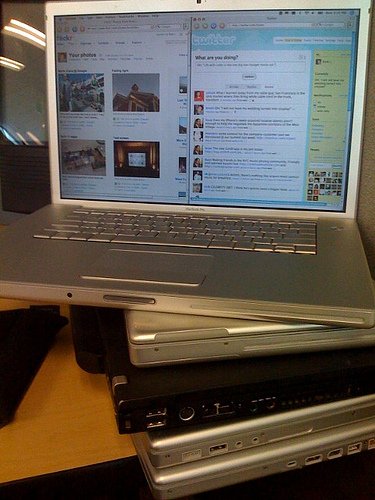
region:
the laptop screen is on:
[53, 9, 347, 208]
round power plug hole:
[178, 406, 194, 424]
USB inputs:
[306, 446, 345, 463]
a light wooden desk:
[2, 331, 134, 482]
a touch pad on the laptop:
[88, 248, 214, 289]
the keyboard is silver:
[36, 204, 318, 253]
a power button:
[330, 224, 342, 230]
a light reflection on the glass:
[2, 21, 43, 73]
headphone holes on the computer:
[235, 437, 258, 447]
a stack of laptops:
[108, 321, 371, 494]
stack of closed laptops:
[100, 308, 373, 499]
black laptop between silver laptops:
[101, 315, 373, 436]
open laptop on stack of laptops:
[0, 0, 374, 328]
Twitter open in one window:
[188, 15, 359, 211]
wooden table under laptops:
[0, 296, 147, 495]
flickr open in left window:
[55, 17, 191, 198]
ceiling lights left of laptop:
[0, 14, 46, 75]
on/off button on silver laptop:
[331, 221, 347, 233]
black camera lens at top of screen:
[192, 0, 205, 6]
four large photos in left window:
[60, 62, 164, 182]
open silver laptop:
[2, 3, 374, 329]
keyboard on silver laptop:
[28, 200, 327, 271]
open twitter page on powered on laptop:
[188, 15, 353, 210]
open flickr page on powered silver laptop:
[52, 20, 189, 203]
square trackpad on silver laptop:
[67, 234, 232, 298]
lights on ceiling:
[1, 10, 46, 90]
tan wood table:
[1, 296, 145, 499]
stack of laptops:
[70, 300, 373, 499]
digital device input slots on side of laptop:
[281, 429, 372, 480]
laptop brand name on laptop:
[179, 202, 215, 213]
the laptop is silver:
[13, 184, 324, 317]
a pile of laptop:
[158, 250, 309, 489]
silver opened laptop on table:
[0, 6, 373, 329]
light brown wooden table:
[22, 404, 108, 459]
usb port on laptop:
[142, 405, 169, 420]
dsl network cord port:
[200, 398, 216, 418]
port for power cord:
[180, 403, 198, 421]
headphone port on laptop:
[235, 439, 243, 449]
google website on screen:
[190, 16, 348, 211]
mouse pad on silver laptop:
[83, 247, 208, 289]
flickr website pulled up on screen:
[57, 18, 187, 209]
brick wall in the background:
[3, 148, 48, 208]